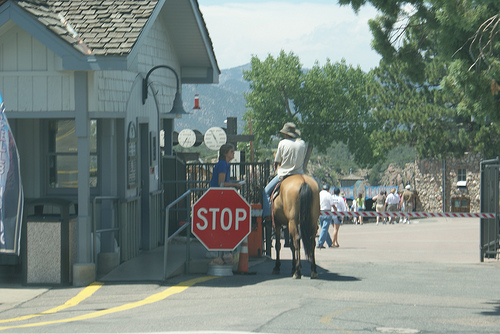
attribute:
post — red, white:
[316, 201, 496, 231]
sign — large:
[185, 182, 257, 255]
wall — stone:
[208, 156, 485, 224]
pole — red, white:
[320, 208, 499, 220]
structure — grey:
[2, 2, 232, 281]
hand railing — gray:
[165, 188, 187, 275]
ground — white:
[421, 145, 446, 161]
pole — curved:
[69, 68, 91, 290]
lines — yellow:
[0, 248, 185, 332]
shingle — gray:
[95, 46, 103, 55]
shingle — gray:
[60, 32, 77, 44]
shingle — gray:
[35, 14, 50, 24]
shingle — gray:
[111, 23, 131, 29]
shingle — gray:
[133, 11, 149, 19]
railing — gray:
[152, 169, 207, 291]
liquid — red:
[190, 92, 203, 108]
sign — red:
[185, 185, 252, 257]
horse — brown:
[276, 174, 321, 279]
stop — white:
[196, 204, 249, 230]